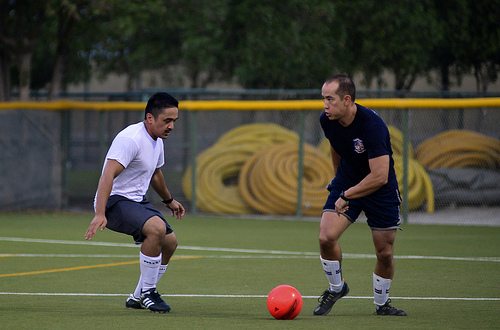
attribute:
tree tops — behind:
[1, 1, 498, 94]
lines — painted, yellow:
[3, 247, 77, 286]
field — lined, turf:
[1, 205, 487, 329]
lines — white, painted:
[0, 288, 497, 305]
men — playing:
[270, 60, 435, 302]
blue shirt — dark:
[301, 122, 471, 198]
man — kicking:
[301, 69, 405, 322]